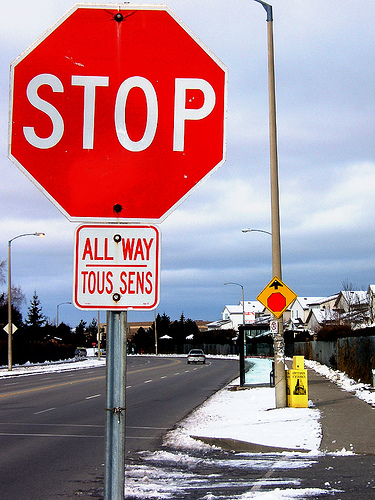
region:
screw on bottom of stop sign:
[109, 200, 128, 214]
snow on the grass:
[219, 408, 312, 434]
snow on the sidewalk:
[274, 480, 347, 498]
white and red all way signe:
[74, 222, 163, 311]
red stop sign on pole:
[2, 3, 235, 225]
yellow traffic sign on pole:
[256, 275, 301, 322]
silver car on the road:
[186, 344, 208, 365]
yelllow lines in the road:
[1, 370, 103, 394]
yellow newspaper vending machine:
[286, 353, 312, 411]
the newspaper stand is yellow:
[289, 348, 310, 409]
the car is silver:
[178, 345, 209, 365]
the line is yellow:
[39, 382, 61, 389]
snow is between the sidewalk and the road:
[217, 406, 270, 435]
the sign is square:
[73, 220, 164, 315]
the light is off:
[234, 223, 251, 236]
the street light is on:
[30, 228, 49, 239]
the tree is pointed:
[22, 283, 50, 345]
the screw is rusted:
[104, 197, 127, 215]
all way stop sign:
[12, 10, 216, 336]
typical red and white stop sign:
[8, 0, 247, 226]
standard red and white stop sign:
[7, 1, 234, 225]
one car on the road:
[132, 336, 237, 441]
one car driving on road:
[137, 344, 229, 437]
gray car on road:
[144, 345, 218, 426]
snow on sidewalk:
[186, 393, 324, 490]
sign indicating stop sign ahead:
[252, 264, 304, 327]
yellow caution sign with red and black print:
[252, 268, 301, 331]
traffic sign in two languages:
[61, 215, 161, 313]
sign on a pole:
[68, 182, 179, 378]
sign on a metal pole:
[58, 218, 214, 437]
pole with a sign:
[62, 210, 189, 394]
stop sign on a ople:
[47, 166, 199, 442]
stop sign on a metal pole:
[33, 156, 129, 388]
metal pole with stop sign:
[41, 162, 227, 419]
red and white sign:
[25, 143, 208, 307]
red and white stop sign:
[46, 81, 229, 338]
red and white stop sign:
[9, 1, 227, 499]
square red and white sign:
[77, 223, 162, 310]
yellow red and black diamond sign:
[257, 276, 297, 318]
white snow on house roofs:
[207, 285, 373, 330]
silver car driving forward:
[188, 347, 207, 362]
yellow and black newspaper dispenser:
[286, 355, 308, 408]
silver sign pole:
[104, 309, 125, 499]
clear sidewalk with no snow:
[270, 353, 374, 451]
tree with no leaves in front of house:
[323, 276, 371, 336]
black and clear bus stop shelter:
[238, 323, 280, 387]